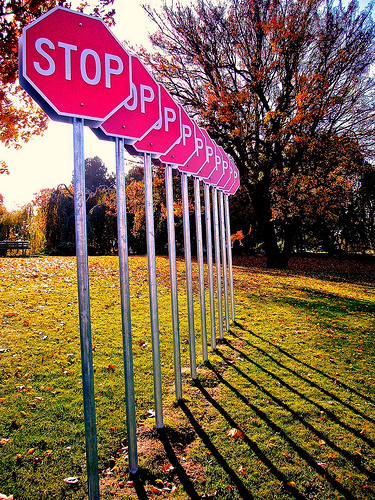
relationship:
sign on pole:
[29, 19, 157, 127] [62, 156, 124, 316]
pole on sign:
[62, 156, 124, 316] [29, 19, 157, 127]